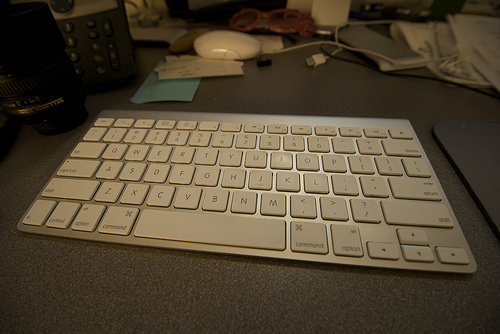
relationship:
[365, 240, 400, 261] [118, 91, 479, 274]
arrow keys in corner of keyboard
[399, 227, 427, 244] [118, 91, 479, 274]
keys in corner of keyboard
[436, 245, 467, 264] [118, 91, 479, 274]
keys in corner of keyboard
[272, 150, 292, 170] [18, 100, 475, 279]
i key on keyboard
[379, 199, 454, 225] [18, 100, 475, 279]
shift key on keyboard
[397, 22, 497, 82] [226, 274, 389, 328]
papers on desk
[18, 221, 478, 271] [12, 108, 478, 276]
edge of keyboard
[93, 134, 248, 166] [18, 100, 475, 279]
keys on keyboard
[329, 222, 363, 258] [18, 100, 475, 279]
button on keyboard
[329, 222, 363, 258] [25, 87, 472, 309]
button on keyboard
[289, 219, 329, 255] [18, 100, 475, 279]
button on keyboard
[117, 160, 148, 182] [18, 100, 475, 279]
button on keyboard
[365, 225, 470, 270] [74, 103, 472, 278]
arrow keys on keyboard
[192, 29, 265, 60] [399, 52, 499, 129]
mouse on desk